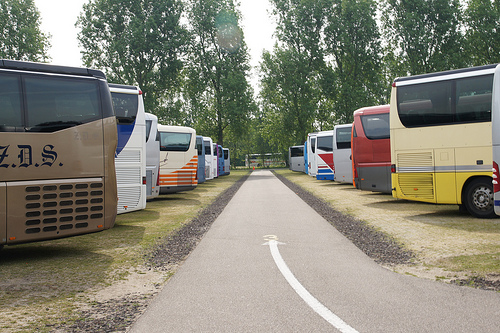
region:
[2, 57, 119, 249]
a brown rv with the initials Z.D.S.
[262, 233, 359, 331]
a white arrow painted on the road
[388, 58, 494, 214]
a white and yellow rv with a silver stripe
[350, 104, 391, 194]
a red recreational vehicle with a grey fender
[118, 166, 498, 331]
a small one lane asphalt road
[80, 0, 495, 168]
a large group of tall trees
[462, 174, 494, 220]
a black tire with a silver rim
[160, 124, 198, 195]
a white rv with orange stripes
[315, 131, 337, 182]
a white rv with blue and red stripes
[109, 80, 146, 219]
a white rv with a blue stripe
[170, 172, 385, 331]
this is a road way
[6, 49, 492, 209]
the buses are parked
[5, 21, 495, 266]
buses are parked on both sides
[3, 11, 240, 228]
a row of buses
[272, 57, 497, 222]
another row of buses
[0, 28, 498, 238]
there are two rows of buses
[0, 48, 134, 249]
this bus is black and brown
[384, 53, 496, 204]
this bus is black and yellow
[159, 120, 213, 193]
this bus has orange stripes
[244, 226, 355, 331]
a white arrow on the pavement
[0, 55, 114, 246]
a brown and black bus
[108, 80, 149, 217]
a white and blue bus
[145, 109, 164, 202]
a grey bus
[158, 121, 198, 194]
a white bus with orange stripes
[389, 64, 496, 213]
a tan and yellow bus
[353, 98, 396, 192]
a red and grey bus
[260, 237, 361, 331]
a white arrow in a road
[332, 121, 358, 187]
a silvery grey bus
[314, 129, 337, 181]
a white bus with red and blue markings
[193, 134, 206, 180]
a grey blue bus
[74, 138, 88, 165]
brown paint on bus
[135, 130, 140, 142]
white paint on bus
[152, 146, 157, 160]
grey paint on bus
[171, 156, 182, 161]
off white paint on bus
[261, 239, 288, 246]
arrow on street line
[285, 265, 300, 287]
white line in street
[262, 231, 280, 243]
number three on street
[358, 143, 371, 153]
red paint on bus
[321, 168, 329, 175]
blue paint on bus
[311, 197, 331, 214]
grey rocks by grass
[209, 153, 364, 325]
road is dark grey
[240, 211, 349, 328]
white line on road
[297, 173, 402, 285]
dark grey gravel near road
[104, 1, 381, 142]
green trees in background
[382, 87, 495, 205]
yellow RV near road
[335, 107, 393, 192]
red RV near road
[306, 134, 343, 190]
red white and blue RV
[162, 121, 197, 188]
orange and white RV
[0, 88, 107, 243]
brown and black RV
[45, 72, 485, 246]
two rows of RVs